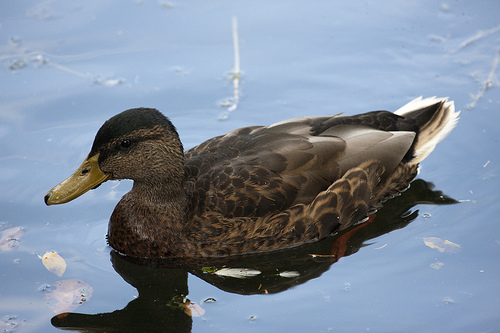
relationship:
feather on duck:
[230, 145, 343, 203] [41, 92, 460, 262]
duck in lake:
[41, 92, 460, 262] [22, 3, 499, 93]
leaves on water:
[31, 250, 78, 283] [0, 1, 499, 331]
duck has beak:
[41, 92, 460, 262] [42, 163, 107, 206]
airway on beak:
[80, 167, 92, 177] [42, 163, 107, 206]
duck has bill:
[41, 92, 460, 262] [8, 120, 169, 233]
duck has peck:
[41, 92, 460, 262] [47, 169, 97, 207]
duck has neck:
[41, 92, 460, 262] [131, 170, 182, 190]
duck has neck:
[41, 92, 460, 262] [128, 154, 198, 196]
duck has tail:
[41, 92, 460, 262] [391, 90, 461, 170]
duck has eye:
[41, 92, 460, 262] [119, 132, 135, 154]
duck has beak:
[41, 92, 460, 262] [41, 141, 118, 212]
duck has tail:
[41, 92, 460, 262] [387, 85, 466, 165]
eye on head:
[119, 132, 135, 154] [88, 110, 185, 177]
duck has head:
[41, 92, 460, 262] [88, 110, 185, 177]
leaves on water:
[31, 250, 78, 283] [168, 22, 356, 122]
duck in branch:
[41, 92, 460, 262] [221, 12, 246, 120]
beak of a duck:
[45, 163, 109, 206] [65, 62, 424, 274]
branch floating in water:
[221, 12, 246, 120] [0, 1, 499, 331]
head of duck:
[39, 103, 193, 211] [41, 92, 460, 262]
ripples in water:
[0, 3, 473, 108] [0, 1, 499, 331]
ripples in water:
[387, 244, 429, 295] [0, 1, 499, 331]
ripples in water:
[0, 3, 473, 108] [13, 40, 488, 319]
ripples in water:
[323, 11, 478, 87] [363, 36, 406, 68]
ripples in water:
[0, 3, 473, 108] [104, 21, 238, 103]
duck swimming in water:
[41, 92, 460, 262] [0, 1, 499, 331]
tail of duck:
[396, 91, 461, 162] [41, 92, 460, 262]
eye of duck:
[118, 132, 137, 159] [28, 101, 492, 295]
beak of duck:
[42, 163, 107, 206] [41, 92, 460, 262]